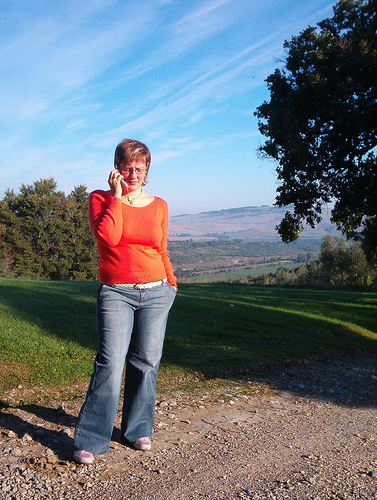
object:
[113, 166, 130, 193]
phone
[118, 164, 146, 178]
glasses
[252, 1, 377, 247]
tree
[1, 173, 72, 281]
tree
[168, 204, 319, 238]
hills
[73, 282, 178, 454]
blue jeans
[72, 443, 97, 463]
feet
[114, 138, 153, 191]
hair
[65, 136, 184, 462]
lady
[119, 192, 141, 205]
jewelry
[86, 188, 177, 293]
shirt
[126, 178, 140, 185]
mouth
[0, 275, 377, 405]
grass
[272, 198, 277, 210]
leaves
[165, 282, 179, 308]
jean pocket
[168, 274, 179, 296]
hand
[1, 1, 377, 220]
sky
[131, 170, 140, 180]
nose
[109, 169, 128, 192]
cell phone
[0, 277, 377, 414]
shadow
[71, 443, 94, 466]
shoe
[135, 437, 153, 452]
shoe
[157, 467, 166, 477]
rocks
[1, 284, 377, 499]
ground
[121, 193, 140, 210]
chain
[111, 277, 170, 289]
belt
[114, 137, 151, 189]
head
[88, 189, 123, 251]
arm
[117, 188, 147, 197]
neck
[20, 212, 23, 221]
leaves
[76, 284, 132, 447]
legs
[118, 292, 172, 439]
leg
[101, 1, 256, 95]
clouds